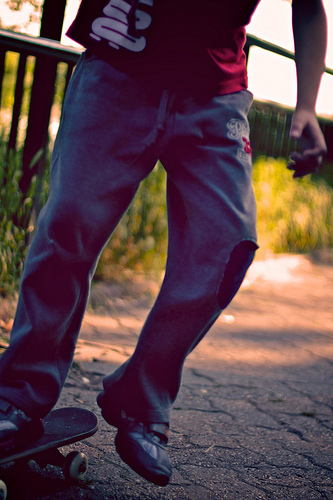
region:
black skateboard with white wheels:
[1, 408, 97, 498]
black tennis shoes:
[0, 402, 171, 480]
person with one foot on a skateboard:
[0, 1, 327, 481]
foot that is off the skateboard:
[104, 395, 179, 483]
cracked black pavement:
[2, 265, 331, 497]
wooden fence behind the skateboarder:
[0, 35, 331, 169]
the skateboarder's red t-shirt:
[63, 2, 256, 91]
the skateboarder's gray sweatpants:
[3, 53, 257, 414]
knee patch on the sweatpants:
[218, 238, 260, 312]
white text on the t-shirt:
[89, 0, 150, 54]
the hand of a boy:
[287, 105, 330, 182]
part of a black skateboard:
[0, 400, 95, 492]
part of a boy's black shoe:
[91, 388, 176, 483]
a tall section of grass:
[0, 124, 329, 287]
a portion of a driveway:
[0, 245, 330, 495]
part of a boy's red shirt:
[65, 1, 262, 91]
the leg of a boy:
[98, 93, 260, 412]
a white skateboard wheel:
[60, 450, 92, 479]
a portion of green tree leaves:
[5, 0, 44, 13]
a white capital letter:
[93, 16, 146, 51]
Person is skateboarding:
[3, 366, 217, 486]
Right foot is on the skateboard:
[8, 348, 89, 461]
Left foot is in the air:
[99, 345, 205, 482]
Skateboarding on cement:
[213, 350, 329, 496]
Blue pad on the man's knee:
[210, 224, 263, 320]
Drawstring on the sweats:
[128, 70, 194, 147]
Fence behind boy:
[5, 21, 77, 175]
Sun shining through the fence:
[4, 55, 58, 145]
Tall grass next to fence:
[270, 171, 328, 246]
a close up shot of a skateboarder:
[12, 289, 261, 488]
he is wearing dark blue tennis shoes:
[90, 359, 202, 489]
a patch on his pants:
[200, 218, 293, 322]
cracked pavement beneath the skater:
[200, 382, 328, 486]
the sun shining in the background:
[218, 223, 331, 348]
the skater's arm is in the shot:
[279, 5, 328, 177]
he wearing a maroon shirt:
[67, 9, 259, 89]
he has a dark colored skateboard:
[3, 409, 112, 494]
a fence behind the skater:
[1, 24, 80, 205]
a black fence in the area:
[254, 97, 332, 181]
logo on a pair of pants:
[227, 114, 259, 174]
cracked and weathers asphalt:
[219, 391, 316, 472]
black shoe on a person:
[102, 389, 203, 488]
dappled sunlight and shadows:
[242, 300, 324, 399]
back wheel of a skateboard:
[63, 447, 95, 479]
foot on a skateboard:
[2, 380, 94, 474]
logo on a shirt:
[77, 6, 141, 56]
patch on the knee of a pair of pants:
[224, 232, 260, 301]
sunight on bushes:
[261, 168, 318, 246]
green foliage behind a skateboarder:
[2, 152, 31, 234]